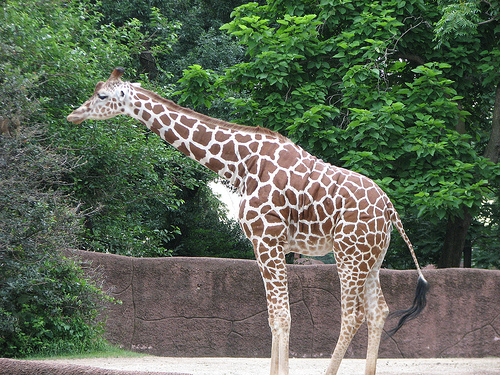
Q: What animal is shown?
A: Giraffe.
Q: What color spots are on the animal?
A: Brown.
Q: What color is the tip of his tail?
A: Black.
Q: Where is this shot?
A: Zoo.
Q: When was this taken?
A: Daytime.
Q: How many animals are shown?
A: 1.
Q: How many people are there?
A: 0.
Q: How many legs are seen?
A: 4.